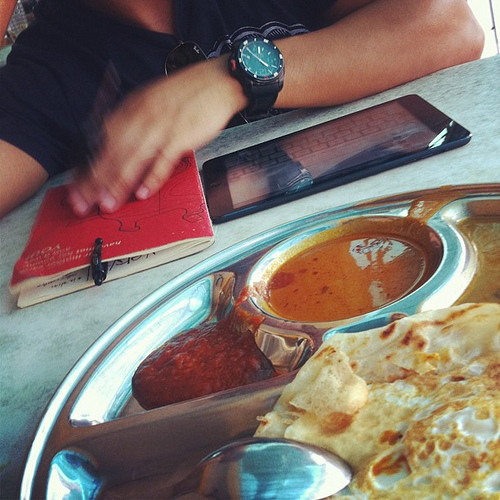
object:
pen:
[91, 238, 107, 287]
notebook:
[8, 149, 215, 309]